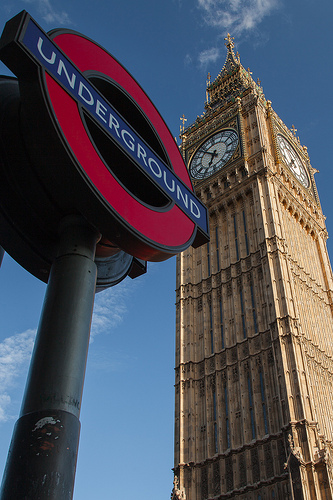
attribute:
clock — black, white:
[187, 125, 239, 179]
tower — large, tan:
[170, 30, 332, 499]